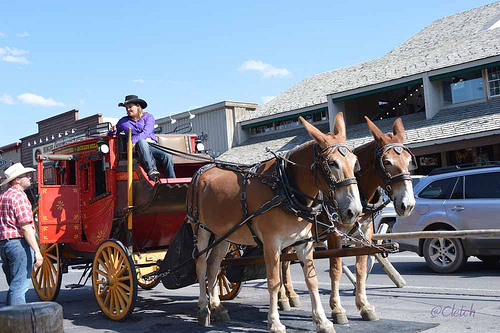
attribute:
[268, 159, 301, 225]
harness — black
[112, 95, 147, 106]
hat — black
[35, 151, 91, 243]
door — opened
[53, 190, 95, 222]
carriage — red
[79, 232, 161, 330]
wheel — yellow, black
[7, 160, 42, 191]
hat — white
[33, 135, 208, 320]
stagecoach — red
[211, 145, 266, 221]
mules — brown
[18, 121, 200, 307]
stagecoach — replica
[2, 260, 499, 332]
street — city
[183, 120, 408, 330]
horse — brown, white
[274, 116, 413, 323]
horse — brown, white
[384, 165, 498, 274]
car — silver, half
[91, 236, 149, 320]
wheel — yellow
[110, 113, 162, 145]
shirt — purple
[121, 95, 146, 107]
hat — black, cowboy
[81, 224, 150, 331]
wheel — black, silver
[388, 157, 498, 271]
car — silver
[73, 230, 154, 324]
wheel — yellow, black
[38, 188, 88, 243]
designs — flower